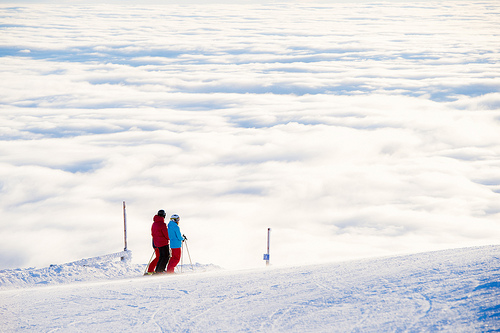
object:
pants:
[154, 243, 170, 273]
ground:
[0, 245, 500, 333]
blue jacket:
[166, 219, 186, 248]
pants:
[166, 246, 182, 273]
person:
[166, 213, 185, 274]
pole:
[184, 241, 195, 271]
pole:
[180, 242, 183, 274]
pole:
[266, 227, 271, 266]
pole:
[121, 200, 127, 252]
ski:
[142, 270, 184, 277]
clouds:
[1, 1, 500, 271]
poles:
[143, 250, 156, 276]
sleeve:
[173, 223, 185, 244]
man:
[150, 209, 171, 274]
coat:
[150, 214, 171, 248]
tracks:
[276, 262, 499, 331]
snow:
[0, 243, 497, 331]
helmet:
[169, 213, 181, 224]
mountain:
[1, 248, 500, 333]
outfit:
[166, 220, 184, 275]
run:
[286, 243, 424, 330]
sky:
[0, 0, 500, 275]